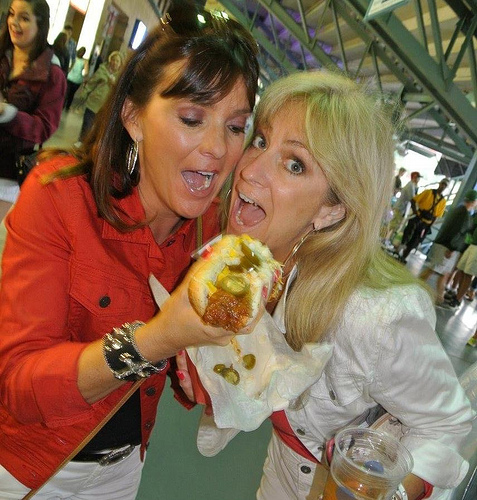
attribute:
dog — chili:
[187, 231, 281, 335]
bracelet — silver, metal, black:
[84, 305, 176, 388]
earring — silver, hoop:
[117, 152, 149, 173]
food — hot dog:
[162, 242, 300, 330]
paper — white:
[199, 348, 338, 436]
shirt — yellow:
[391, 181, 457, 247]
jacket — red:
[0, 154, 233, 413]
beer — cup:
[290, 415, 424, 499]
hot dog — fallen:
[143, 234, 285, 354]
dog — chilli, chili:
[159, 247, 258, 324]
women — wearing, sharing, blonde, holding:
[66, 27, 413, 309]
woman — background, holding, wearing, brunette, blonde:
[114, 49, 416, 291]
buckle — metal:
[89, 429, 144, 476]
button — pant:
[279, 450, 323, 494]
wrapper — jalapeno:
[154, 349, 318, 487]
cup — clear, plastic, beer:
[345, 431, 425, 475]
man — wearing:
[425, 205, 466, 312]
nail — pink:
[197, 246, 226, 267]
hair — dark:
[184, 42, 235, 101]